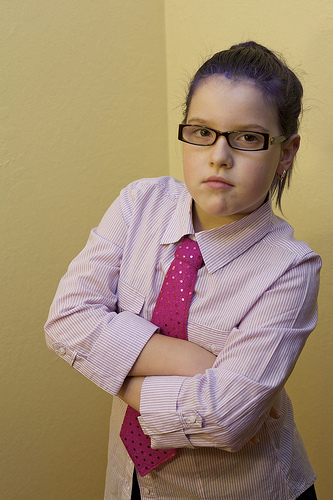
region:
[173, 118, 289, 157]
A pair of eyeglasses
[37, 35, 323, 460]
The girl has her arms crossed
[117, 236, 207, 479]
A pink colored tie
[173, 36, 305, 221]
The girl has brown hair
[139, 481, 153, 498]
A button on a shirt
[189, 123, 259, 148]
A pair of brown eyes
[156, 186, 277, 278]
The collar of a shirt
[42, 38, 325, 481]
Young girl is wearing a tie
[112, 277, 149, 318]
A pocket on the shirt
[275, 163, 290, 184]
An earring on an ear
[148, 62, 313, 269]
the head of a girl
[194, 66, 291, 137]
the forehead of a girl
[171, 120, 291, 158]
the eyes of a girl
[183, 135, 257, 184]
the nose of a girl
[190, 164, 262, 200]
the mouth of a girl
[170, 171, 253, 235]
the lips of a girl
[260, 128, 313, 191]
the ears of a girl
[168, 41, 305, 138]
the hair of a girl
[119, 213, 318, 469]
the arm of a girl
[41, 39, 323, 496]
a little girl with glasses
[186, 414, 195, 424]
white shirt cuff button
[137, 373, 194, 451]
purple and white stripe shirt cuff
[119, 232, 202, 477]
pink sparkly polka dot neck tie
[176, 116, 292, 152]
brown rectangle rimmed glasses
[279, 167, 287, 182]
earring of a little girl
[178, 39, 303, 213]
brunette updo hair style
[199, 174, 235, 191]
lips of a little girl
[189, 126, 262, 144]
a pair of brown eyes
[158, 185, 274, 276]
a purple and white striped shirt collar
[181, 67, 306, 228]
head of the little girl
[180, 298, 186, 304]
polka dot on the tie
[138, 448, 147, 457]
polka dot on the tie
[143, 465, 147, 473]
polka dot on the tie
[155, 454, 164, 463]
polka dot on the tie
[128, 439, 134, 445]
polka dot on the tie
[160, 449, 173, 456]
polka dot on the tie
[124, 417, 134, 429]
polka dot on the tie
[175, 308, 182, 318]
polka dot on the tie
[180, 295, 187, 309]
polka dot on the tie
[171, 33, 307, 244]
head and neck of young girl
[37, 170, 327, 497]
pink and white stripped dress shirt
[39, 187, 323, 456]
folded arms of young girl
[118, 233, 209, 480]
pink tie on young girl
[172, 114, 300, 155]
glasses on young girl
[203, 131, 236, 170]
nose and two nostrils of young girl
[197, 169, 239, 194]
red lips of young girl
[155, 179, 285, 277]
fold down collar on dress shirt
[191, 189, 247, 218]
chin on young girl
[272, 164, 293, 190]
ear ring in young girls left ear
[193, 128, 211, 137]
person has an eye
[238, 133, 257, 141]
person has an eye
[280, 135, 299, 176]
person has an ear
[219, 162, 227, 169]
person has a nostral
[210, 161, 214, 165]
person has a nostral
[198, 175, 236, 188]
person has a mouth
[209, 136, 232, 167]
person has a nose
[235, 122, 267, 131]
person has an eyebrow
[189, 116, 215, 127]
person has an eyebrow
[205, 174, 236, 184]
person has a li0p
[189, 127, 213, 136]
girl has an eye